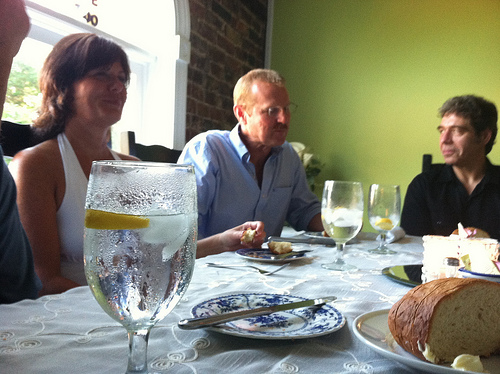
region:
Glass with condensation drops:
[81, 157, 198, 372]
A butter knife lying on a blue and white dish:
[173, 288, 349, 344]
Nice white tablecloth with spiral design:
[1, 230, 436, 371]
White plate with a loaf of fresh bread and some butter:
[350, 275, 498, 372]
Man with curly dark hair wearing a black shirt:
[401, 92, 496, 234]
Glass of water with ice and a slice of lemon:
[80, 157, 200, 372]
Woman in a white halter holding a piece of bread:
[8, 29, 264, 299]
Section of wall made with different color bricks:
[188, 0, 266, 136]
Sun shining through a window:
[0, 2, 191, 149]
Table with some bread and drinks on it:
[11, 163, 498, 371]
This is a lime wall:
[363, 51, 390, 118]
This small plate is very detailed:
[231, 282, 278, 356]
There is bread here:
[443, 283, 465, 341]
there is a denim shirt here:
[208, 140, 235, 212]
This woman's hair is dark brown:
[66, 43, 79, 72]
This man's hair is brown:
[456, 106, 473, 118]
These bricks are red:
[215, 41, 222, 105]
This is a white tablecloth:
[280, 358, 285, 371]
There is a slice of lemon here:
[99, 185, 141, 256]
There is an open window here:
[21, 68, 26, 84]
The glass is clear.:
[367, 172, 404, 259]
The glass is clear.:
[306, 169, 366, 279]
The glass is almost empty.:
[366, 176, 409, 263]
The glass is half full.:
[315, 169, 371, 279]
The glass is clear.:
[75, 150, 205, 372]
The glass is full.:
[76, 148, 201, 372]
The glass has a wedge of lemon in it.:
[76, 153, 206, 373]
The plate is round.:
[186, 280, 346, 350]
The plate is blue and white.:
[188, 280, 348, 345]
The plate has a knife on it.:
[173, 283, 348, 344]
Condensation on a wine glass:
[83, 159, 196, 372]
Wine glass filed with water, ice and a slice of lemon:
[82, 158, 199, 370]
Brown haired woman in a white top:
[10, 31, 266, 296]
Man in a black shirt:
[398, 94, 498, 234]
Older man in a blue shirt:
[171, 65, 342, 232]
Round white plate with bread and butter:
[352, 273, 499, 370]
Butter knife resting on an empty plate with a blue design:
[186, 287, 347, 342]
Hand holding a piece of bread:
[223, 218, 266, 250]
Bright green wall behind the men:
[267, 1, 499, 228]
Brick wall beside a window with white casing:
[1, 0, 271, 138]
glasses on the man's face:
[246, 100, 300, 118]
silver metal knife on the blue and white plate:
[176, 292, 340, 330]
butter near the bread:
[448, 350, 483, 372]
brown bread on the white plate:
[386, 275, 498, 368]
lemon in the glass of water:
[83, 204, 148, 231]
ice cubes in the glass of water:
[139, 214, 193, 260]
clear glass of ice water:
[81, 157, 196, 369]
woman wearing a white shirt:
[53, 132, 125, 286]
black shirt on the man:
[395, 160, 499, 243]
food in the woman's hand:
[237, 223, 263, 248]